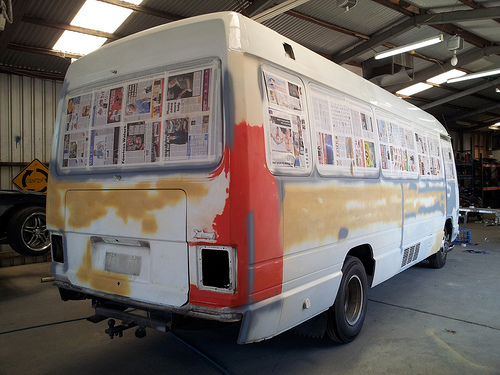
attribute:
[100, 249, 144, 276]
license plate — missing from van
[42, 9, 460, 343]
van — prepared for paint, painted yellow, painted red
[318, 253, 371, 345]
tire — black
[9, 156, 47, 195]
street sign — yellow, black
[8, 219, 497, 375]
floor — cement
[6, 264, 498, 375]
road — gray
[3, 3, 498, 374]
shed — gray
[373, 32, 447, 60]
light — on, on the ceiling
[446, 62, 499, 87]
light — on, on the ceiling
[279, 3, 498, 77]
rods — brown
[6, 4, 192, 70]
rods — brown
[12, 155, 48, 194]
board — yellow, black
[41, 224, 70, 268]
bumper light — missing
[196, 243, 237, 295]
bumper light — missing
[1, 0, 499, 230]
building — made of aluminum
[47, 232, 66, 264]
hole — for tail lights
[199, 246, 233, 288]
hole — for tail lights